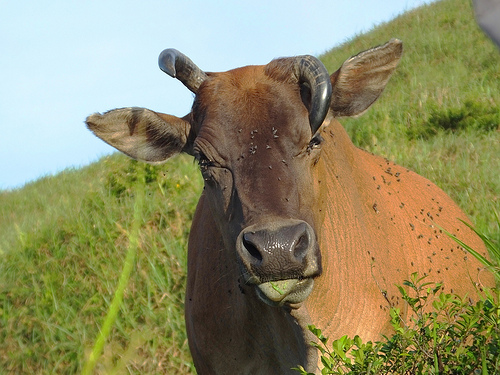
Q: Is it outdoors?
A: Yes, it is outdoors.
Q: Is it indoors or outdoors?
A: It is outdoors.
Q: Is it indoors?
A: No, it is outdoors.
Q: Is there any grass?
A: Yes, there is grass.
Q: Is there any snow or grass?
A: Yes, there is grass.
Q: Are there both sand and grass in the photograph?
A: No, there is grass but no sand.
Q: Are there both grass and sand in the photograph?
A: No, there is grass but no sand.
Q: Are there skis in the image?
A: No, there are no skis.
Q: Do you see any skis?
A: No, there are no skis.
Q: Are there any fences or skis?
A: No, there are no skis or fences.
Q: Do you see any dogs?
A: No, there are no dogs.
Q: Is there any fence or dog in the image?
A: No, there are no dogs or fences.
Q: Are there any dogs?
A: No, there are no dogs.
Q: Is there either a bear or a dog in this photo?
A: No, there are no dogs or bears.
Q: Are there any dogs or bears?
A: No, there are no dogs or bears.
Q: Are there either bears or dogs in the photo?
A: No, there are no dogs or bears.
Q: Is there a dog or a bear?
A: No, there are no dogs or bears.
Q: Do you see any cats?
A: No, there are no cats.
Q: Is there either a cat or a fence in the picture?
A: No, there are no cats or fences.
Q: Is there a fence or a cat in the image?
A: No, there are no cats or fences.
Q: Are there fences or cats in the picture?
A: No, there are no cats or fences.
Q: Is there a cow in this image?
A: Yes, there is a cow.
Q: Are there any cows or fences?
A: Yes, there is a cow.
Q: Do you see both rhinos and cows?
A: No, there is a cow but no rhinos.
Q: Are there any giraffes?
A: No, there are no giraffes.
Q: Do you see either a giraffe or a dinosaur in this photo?
A: No, there are no giraffes or dinosaurs.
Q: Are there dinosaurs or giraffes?
A: No, there are no giraffes or dinosaurs.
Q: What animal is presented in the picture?
A: The animal is a cow.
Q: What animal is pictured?
A: The animal is a cow.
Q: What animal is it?
A: The animal is a cow.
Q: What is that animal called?
A: This is a cow.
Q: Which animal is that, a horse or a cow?
A: This is a cow.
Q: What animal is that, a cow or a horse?
A: This is a cow.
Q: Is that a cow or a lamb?
A: That is a cow.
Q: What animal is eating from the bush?
A: The cow is eating from the bush.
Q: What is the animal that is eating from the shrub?
A: The animal is a cow.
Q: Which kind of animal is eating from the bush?
A: The animal is a cow.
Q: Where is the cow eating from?
A: The cow is eating from the shrub.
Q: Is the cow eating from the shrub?
A: Yes, the cow is eating from the shrub.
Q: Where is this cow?
A: The cow is on the grass.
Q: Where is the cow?
A: The cow is on the grass.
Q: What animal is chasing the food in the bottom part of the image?
A: The cow is chasing the food.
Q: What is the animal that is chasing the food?
A: The animal is a cow.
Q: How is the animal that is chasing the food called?
A: The animal is a cow.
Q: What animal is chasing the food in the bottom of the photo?
A: The animal is a cow.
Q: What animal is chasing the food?
A: The animal is a cow.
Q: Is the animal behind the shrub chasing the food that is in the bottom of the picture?
A: Yes, the cow is chasing the food.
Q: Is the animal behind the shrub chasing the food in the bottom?
A: Yes, the cow is chasing the food.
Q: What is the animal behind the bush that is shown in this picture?
A: The animal is a cow.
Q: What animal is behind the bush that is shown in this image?
A: The animal is a cow.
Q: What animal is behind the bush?
A: The animal is a cow.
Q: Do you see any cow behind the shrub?
A: Yes, there is a cow behind the shrub.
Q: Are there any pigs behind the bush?
A: No, there is a cow behind the bush.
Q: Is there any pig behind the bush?
A: No, there is a cow behind the bush.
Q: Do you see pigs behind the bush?
A: No, there is a cow behind the bush.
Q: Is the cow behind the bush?
A: Yes, the cow is behind the bush.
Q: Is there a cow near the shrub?
A: Yes, there is a cow near the shrub.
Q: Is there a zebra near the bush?
A: No, there is a cow near the bush.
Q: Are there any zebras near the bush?
A: No, there is a cow near the bush.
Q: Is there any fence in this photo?
A: No, there are no fences.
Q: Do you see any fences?
A: No, there are no fences.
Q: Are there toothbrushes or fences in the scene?
A: No, there are no fences or toothbrushes.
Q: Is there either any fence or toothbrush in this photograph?
A: No, there are no fences or toothbrushes.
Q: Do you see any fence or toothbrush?
A: No, there are no fences or toothbrushes.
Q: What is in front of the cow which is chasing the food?
A: The shrub is in front of the cow.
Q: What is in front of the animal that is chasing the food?
A: The shrub is in front of the cow.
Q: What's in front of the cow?
A: The shrub is in front of the cow.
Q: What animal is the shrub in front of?
A: The shrub is in front of the cow.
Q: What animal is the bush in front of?
A: The shrub is in front of the cow.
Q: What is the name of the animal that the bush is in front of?
A: The animal is a cow.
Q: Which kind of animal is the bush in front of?
A: The bush is in front of the cow.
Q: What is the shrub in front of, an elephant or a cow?
A: The shrub is in front of a cow.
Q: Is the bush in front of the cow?
A: Yes, the bush is in front of the cow.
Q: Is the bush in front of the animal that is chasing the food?
A: Yes, the bush is in front of the cow.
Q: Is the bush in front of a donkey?
A: No, the bush is in front of the cow.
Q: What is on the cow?
A: The shrub is on the cow.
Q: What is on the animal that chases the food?
A: The shrub is on the cow.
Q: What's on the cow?
A: The shrub is on the cow.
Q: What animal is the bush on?
A: The bush is on the cow.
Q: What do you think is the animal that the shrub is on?
A: The animal is a cow.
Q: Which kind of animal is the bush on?
A: The shrub is on the cow.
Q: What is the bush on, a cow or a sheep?
A: The bush is on a cow.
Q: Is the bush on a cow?
A: Yes, the bush is on a cow.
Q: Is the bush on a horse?
A: No, the bush is on a cow.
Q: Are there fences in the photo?
A: No, there are no fences.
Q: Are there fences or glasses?
A: No, there are no fences or glasses.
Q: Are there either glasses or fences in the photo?
A: No, there are no fences or glasses.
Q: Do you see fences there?
A: No, there are no fences.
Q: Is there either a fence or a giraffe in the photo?
A: No, there are no fences or giraffes.